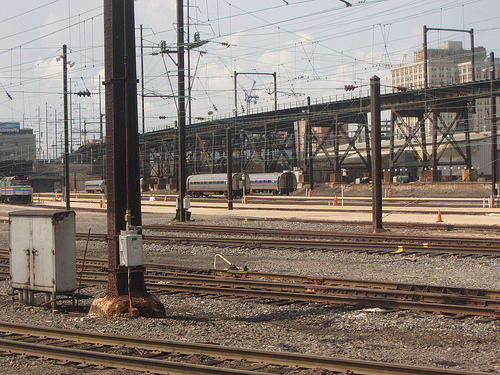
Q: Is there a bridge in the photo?
A: Yes, there is a bridge.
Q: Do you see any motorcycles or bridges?
A: Yes, there is a bridge.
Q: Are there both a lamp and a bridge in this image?
A: No, there is a bridge but no lamps.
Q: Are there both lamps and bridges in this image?
A: No, there is a bridge but no lamps.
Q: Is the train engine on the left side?
A: Yes, the train engine is on the left of the image.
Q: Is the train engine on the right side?
A: No, the train engine is on the left of the image.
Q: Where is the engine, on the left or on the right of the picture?
A: The engine is on the left of the image.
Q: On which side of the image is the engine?
A: The engine is on the left of the image.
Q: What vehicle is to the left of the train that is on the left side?
A: The vehicle is a locomotive.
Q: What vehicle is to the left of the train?
A: The vehicle is a locomotive.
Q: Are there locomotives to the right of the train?
A: No, the locomotive is to the left of the train.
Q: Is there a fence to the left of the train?
A: No, there is a locomotive to the left of the train.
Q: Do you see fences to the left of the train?
A: No, there is a locomotive to the left of the train.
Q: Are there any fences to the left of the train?
A: No, there is a locomotive to the left of the train.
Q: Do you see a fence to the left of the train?
A: No, there is a locomotive to the left of the train.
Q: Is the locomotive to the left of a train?
A: Yes, the locomotive is to the left of a train.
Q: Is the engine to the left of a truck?
A: No, the engine is to the left of a train.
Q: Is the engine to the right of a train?
A: No, the engine is to the left of a train.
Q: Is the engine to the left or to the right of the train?
A: The engine is to the left of the train.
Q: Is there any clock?
A: No, there are no clocks.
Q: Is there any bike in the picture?
A: No, there are no bikes.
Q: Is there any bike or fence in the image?
A: No, there are no bikes or fences.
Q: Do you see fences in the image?
A: No, there are no fences.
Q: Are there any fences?
A: No, there are no fences.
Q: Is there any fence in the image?
A: No, there are no fences.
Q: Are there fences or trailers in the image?
A: No, there are no fences or trailers.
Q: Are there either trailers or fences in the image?
A: No, there are no fences or trailers.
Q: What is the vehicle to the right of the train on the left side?
A: The vehicle is a train car.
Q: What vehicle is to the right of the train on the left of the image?
A: The vehicle is a train car.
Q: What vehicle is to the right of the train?
A: The vehicle is a train car.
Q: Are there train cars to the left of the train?
A: No, the train car is to the right of the train.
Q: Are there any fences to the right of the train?
A: No, there is a train car to the right of the train.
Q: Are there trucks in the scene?
A: No, there are no trucks.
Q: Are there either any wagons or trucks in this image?
A: No, there are no trucks or wagons.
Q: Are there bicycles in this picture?
A: No, there are no bicycles.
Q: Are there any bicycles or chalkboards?
A: No, there are no bicycles or chalkboards.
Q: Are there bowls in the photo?
A: No, there are no bowls.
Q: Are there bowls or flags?
A: No, there are no bowls or flags.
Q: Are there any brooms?
A: No, there are no brooms.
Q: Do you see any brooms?
A: No, there are no brooms.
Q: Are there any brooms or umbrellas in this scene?
A: No, there are no brooms or umbrellas.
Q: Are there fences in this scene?
A: No, there are no fences.